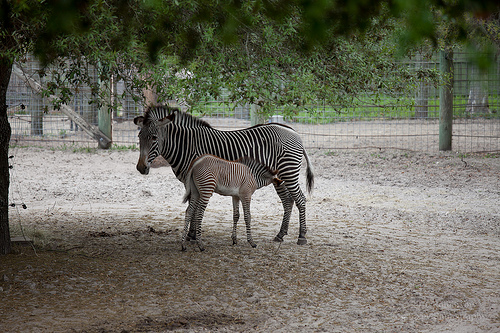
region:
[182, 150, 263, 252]
the zebra is small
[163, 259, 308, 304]
foot prints are on the sand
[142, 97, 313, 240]
the zebra is black and white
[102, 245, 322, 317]
the sand is brown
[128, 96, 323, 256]
the zebras are under the tree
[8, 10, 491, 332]
the scene is outdoors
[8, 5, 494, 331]
the photo ws taken during the day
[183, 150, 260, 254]
the calf is suckling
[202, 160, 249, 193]
the skin is light brown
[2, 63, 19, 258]
the tree bark is dark brown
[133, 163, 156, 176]
Zebra has black nose.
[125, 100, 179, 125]
Zebra has black and white ears.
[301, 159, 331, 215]
Black hair on tip of zebra's tail.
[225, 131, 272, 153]
Zebra is black and white.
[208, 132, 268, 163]
Zebra is covered in stripes.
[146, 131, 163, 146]
Zebra has dark eye.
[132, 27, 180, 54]
Green leaves on tree.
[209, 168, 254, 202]
Zebra is covered in stripes.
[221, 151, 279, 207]
Zebra is nursing from mother.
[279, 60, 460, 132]
Zebras are standing in fenced in area.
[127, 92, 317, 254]
this is a zebra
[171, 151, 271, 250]
the younger zebra is feeding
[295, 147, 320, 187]
this is the tail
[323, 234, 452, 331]
this is the ground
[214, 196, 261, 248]
these are the legs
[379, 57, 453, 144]
this is a fence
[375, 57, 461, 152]
the fence is metallic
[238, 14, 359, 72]
these are the leaves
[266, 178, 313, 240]
the leave are short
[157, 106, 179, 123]
this is the ear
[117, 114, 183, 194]
the head of a zebra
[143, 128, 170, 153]
the black eye of a zebra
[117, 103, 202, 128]
the ears of a zebra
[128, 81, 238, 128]
the main of a zebra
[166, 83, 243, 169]
the neck of a zebra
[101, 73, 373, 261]
two zebras in an enclosure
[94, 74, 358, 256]
two zebras standing on sparse grass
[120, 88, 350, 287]
zebras have black and white stripes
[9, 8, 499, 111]
tree branches hanging down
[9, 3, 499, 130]
leaves on trees are green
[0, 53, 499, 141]
fence is made of metal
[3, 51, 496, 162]
fence has wooden posts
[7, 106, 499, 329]
ground is brown and appears dry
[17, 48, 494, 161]
fence posts are brown